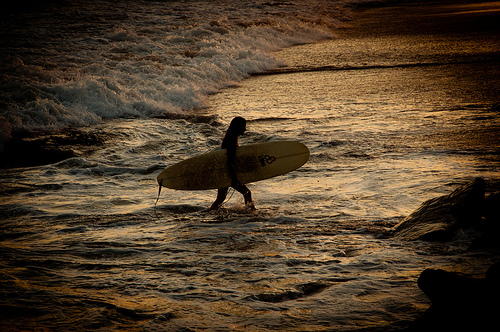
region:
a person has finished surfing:
[8, 93, 475, 243]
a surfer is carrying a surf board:
[150, 115, 305, 220]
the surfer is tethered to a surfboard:
[148, 115, 304, 221]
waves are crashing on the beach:
[12, 60, 485, 315]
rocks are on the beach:
[352, 68, 497, 328]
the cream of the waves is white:
[10, 16, 355, 149]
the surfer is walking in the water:
[201, 111, 256, 216]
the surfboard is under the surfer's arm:
[207, 115, 260, 217]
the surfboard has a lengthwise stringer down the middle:
[156, 135, 311, 192]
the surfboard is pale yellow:
[155, 138, 312, 191]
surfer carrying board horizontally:
[102, 65, 359, 236]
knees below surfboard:
[166, 170, 306, 230]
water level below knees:
[175, 185, 281, 270]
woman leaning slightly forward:
[206, 110, 271, 165]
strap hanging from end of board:
[146, 160, 166, 225]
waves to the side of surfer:
[85, 22, 317, 227]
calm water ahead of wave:
[235, 61, 455, 122]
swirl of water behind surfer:
[91, 96, 216, 166]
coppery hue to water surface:
[61, 220, 387, 302]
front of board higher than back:
[130, 108, 331, 214]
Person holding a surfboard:
[136, 107, 317, 223]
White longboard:
[145, 137, 324, 194]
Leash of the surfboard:
[147, 175, 244, 220]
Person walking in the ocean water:
[24, 14, 414, 307]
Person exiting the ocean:
[47, 29, 446, 295]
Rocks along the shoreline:
[385, 155, 497, 330]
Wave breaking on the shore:
[5, 9, 345, 111]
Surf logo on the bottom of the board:
[252, 150, 281, 176]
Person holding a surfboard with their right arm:
[150, 106, 310, 223]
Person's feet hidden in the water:
[192, 193, 269, 224]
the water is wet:
[115, 233, 247, 327]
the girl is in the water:
[148, 103, 325, 215]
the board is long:
[147, 140, 324, 197]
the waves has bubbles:
[60, 40, 235, 135]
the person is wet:
[210, 97, 267, 237]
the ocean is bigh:
[122, 238, 281, 314]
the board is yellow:
[150, 135, 325, 195]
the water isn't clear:
[144, 22, 442, 110]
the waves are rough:
[86, 36, 248, 121]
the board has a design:
[151, 141, 324, 186]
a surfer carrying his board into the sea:
[122, 91, 416, 237]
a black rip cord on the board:
[154, 183, 165, 217]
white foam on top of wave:
[78, 70, 148, 105]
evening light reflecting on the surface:
[109, 286, 226, 321]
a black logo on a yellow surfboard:
[259, 149, 297, 166]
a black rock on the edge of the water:
[416, 255, 490, 318]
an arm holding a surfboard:
[224, 140, 243, 182]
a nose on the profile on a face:
[243, 126, 245, 133]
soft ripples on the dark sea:
[352, 85, 405, 124]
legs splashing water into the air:
[204, 201, 271, 211]